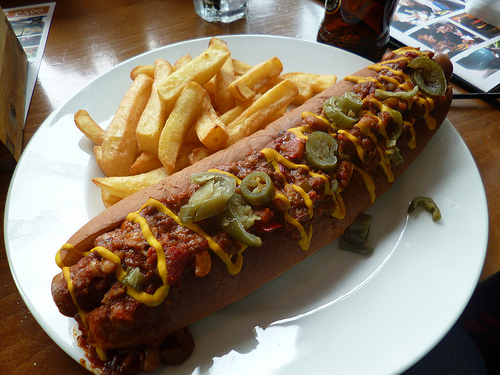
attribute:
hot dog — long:
[49, 51, 454, 318]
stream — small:
[64, 242, 156, 303]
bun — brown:
[55, 53, 407, 268]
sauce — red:
[81, 227, 176, 325]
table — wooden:
[42, 28, 492, 353]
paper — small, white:
[0, 1, 60, 133]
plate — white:
[13, 23, 494, 373]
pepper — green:
[239, 167, 277, 197]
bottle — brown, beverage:
[306, 0, 412, 65]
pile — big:
[75, 36, 336, 178]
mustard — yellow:
[55, 58, 436, 351]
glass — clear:
[187, 1, 249, 22]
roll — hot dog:
[47, 46, 460, 355]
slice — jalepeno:
[405, 190, 443, 230]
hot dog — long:
[51, 34, 458, 372]